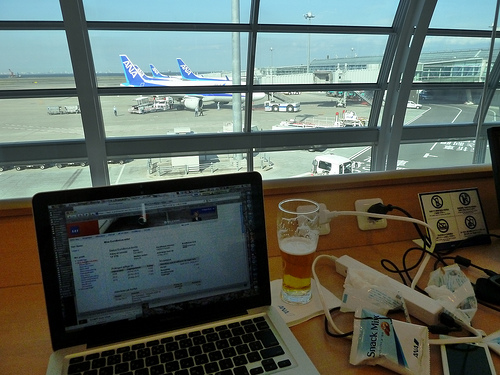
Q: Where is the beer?
A: Next to the computer.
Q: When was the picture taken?
A: Daytime.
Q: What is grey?
A: Window frames.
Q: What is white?
A: Surge protector.